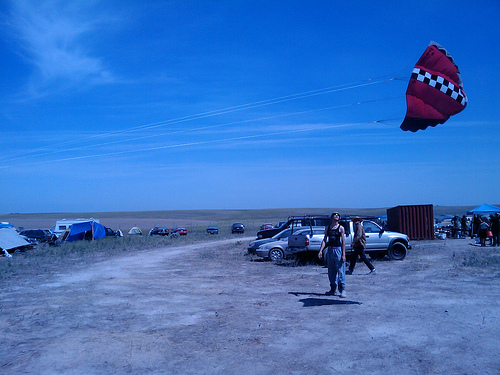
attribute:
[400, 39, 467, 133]
parachute — checkered, purple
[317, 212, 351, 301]
woman — looking up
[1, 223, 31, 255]
tent — green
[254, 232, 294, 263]
car — silver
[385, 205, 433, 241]
container — brown, metallic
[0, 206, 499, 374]
ground — barren, dry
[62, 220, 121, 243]
tent — open, blue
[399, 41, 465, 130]
kite — red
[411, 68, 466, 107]
checkered pattern — white, black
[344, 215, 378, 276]
person — standing, walking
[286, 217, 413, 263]
truck — gray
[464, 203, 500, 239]
gazebo — blue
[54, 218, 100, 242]
camper — parked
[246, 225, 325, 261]
car — parked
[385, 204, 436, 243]
dumpster — rusted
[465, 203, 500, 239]
canopy — blue